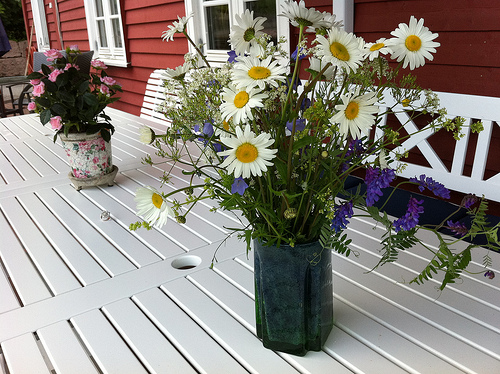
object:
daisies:
[228, 54, 287, 91]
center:
[329, 40, 348, 59]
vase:
[247, 230, 349, 353]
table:
[6, 129, 428, 373]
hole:
[171, 254, 200, 275]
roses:
[43, 67, 69, 85]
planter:
[67, 128, 113, 176]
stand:
[68, 168, 119, 194]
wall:
[25, 2, 497, 133]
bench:
[139, 61, 464, 208]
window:
[87, 3, 128, 66]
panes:
[94, 3, 124, 54]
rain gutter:
[328, 3, 354, 77]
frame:
[177, 0, 298, 68]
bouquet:
[135, 5, 499, 364]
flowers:
[386, 192, 433, 237]